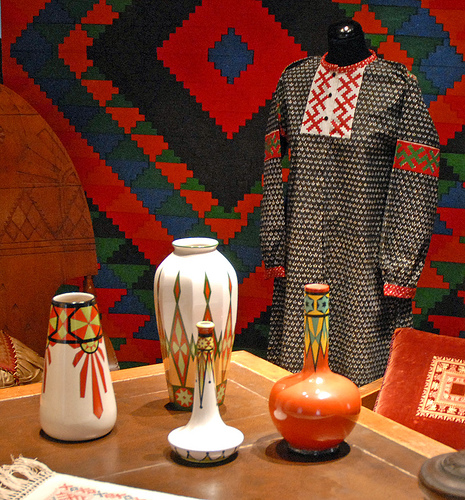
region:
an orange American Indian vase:
[266, 281, 364, 454]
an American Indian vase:
[167, 318, 242, 464]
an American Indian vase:
[154, 235, 241, 408]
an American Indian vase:
[36, 290, 116, 442]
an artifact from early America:
[417, 443, 463, 498]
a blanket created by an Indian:
[0, 449, 203, 497]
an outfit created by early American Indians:
[253, 43, 436, 399]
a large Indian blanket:
[1, 0, 462, 330]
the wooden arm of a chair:
[355, 374, 386, 399]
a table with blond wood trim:
[0, 344, 461, 497]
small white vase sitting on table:
[24, 287, 126, 445]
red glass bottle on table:
[267, 279, 365, 465]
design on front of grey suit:
[296, 60, 371, 151]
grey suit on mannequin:
[251, 41, 437, 304]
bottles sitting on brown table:
[11, 239, 355, 482]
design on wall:
[84, 0, 260, 225]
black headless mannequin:
[312, 11, 375, 64]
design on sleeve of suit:
[372, 273, 419, 300]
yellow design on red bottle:
[302, 295, 331, 358]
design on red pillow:
[420, 351, 463, 424]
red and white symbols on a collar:
[313, 60, 354, 145]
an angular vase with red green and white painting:
[41, 286, 122, 453]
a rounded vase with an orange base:
[275, 283, 365, 442]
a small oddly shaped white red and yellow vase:
[168, 317, 243, 485]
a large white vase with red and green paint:
[158, 222, 243, 384]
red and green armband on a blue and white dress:
[395, 131, 434, 164]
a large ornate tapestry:
[84, 110, 258, 193]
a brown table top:
[110, 430, 149, 479]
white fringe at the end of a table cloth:
[11, 446, 43, 489]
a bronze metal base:
[425, 441, 464, 487]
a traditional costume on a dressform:
[262, 22, 440, 363]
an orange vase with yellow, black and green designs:
[268, 280, 362, 452]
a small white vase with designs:
[169, 318, 244, 468]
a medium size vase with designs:
[37, 288, 118, 444]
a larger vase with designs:
[152, 233, 239, 410]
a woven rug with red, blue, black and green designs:
[0, 1, 463, 359]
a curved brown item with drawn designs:
[0, 81, 98, 368]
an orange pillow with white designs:
[376, 324, 463, 446]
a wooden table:
[2, 346, 459, 498]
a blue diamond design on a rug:
[204, 27, 255, 85]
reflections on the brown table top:
[176, 459, 297, 489]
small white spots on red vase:
[273, 370, 342, 431]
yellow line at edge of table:
[368, 420, 424, 451]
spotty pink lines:
[362, 444, 407, 472]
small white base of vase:
[125, 419, 297, 466]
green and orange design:
[163, 271, 190, 308]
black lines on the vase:
[47, 291, 110, 362]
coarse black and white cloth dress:
[279, 188, 379, 255]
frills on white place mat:
[10, 451, 74, 487]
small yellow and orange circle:
[159, 378, 200, 413]